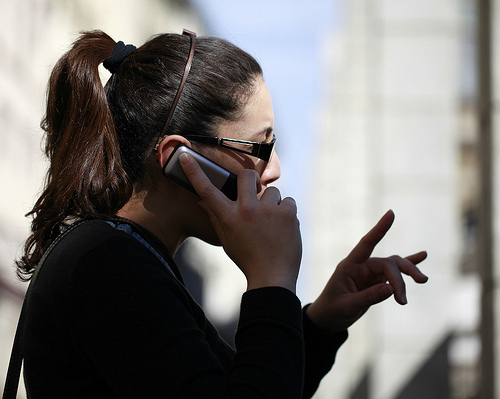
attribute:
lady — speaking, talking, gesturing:
[17, 28, 428, 398]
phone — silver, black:
[163, 144, 238, 198]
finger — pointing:
[351, 210, 395, 260]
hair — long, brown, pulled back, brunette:
[14, 28, 262, 281]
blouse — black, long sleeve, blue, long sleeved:
[23, 218, 347, 399]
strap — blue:
[3, 216, 177, 399]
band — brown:
[161, 30, 195, 152]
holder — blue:
[104, 41, 136, 71]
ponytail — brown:
[15, 24, 116, 282]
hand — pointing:
[307, 209, 426, 327]